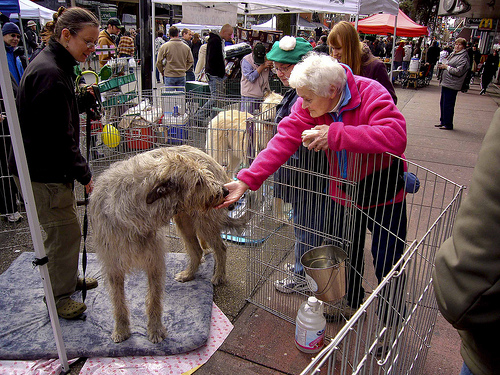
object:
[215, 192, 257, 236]
tail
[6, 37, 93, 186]
jacket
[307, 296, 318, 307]
lid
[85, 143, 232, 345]
dog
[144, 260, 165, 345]
legs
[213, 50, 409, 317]
old man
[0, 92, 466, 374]
cage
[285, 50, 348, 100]
hair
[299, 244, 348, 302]
bucket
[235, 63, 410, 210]
jacket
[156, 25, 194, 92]
man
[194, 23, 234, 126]
man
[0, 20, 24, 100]
man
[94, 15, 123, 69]
man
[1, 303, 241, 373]
floor